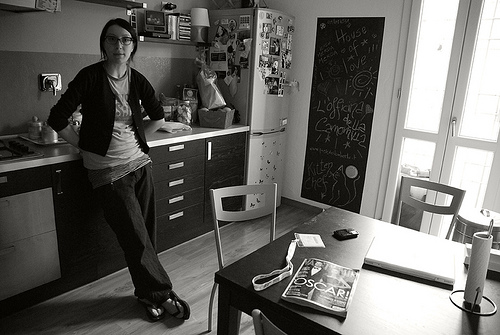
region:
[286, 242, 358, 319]
magazine on the table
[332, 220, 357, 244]
cellphone on the table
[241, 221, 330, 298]
id badge on the table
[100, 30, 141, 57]
woman wearing reading glasses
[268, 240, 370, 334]
magazine on table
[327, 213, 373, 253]
cell phone on table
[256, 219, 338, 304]
badge on table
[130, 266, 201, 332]
lady wearing flip flops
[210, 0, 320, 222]
fridge in kitchen with pictures on it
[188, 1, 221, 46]
lamp on shelf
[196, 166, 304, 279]
chair under table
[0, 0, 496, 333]
A woman standing in a kitchen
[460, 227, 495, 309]
A roll of paper towels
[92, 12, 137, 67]
Woman has on glasses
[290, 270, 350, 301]
"OSCAR!" written on a magazine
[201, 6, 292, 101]
Many pictures and magnets on fridge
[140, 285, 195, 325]
A pair of flip flops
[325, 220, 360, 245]
A cell phone on the table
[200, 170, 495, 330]
Two chairs at a table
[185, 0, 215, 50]
A small lamp on a shelf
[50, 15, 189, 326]
Woman standing against kitchen counter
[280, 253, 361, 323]
Magazine on the table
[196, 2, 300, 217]
Refrigerator in the corner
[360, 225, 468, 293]
Laptop on the table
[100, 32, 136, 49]
Glasses over woman's eyes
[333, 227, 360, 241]
Black mouse on the table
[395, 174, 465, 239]
Chair at the table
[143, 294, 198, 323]
Flip-flops on woman's feet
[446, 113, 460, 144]
Handle on the door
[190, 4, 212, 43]
Small lamp on the shelf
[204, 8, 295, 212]
refrigerator is next to cabinet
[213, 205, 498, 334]
magazine on top of table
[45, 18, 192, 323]
woman wearing black glasses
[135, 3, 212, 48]
lamp on wall shelf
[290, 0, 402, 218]
chalkboard paint on wall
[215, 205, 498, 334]
cell phone on table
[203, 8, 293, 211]
magnets and pictures on refrigerator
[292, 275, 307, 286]
white letter on magazine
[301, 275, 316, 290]
white letter on magazine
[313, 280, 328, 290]
white letter on magazine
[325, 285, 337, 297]
white letter on magazine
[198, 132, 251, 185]
A door for a cabinet.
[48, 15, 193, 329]
Woman standing against the kitchen counter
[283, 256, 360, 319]
Magazine on the table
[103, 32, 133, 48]
Glasses on woman's face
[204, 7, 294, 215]
Refrigerator in the corner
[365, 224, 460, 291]
Laptop on the table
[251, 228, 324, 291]
ID badge on a lanyard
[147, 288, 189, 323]
Flip flops on woman's feet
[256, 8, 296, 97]
Magnets and pictures on the refrigerator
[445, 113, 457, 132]
Handle on the door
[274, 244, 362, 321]
entertainment magazine on kitchen table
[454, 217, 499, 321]
partial roll of paper towels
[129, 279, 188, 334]
flip flop shoes on woman's feet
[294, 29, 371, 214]
chalkboard on wall of kitchen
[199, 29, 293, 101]
photographs on refrigerator door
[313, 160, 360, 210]
chalk drawing of a cat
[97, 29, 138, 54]
glasses on face of woman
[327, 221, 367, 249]
black cellphone on kitchen table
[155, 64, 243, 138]
food piled in corner of counter